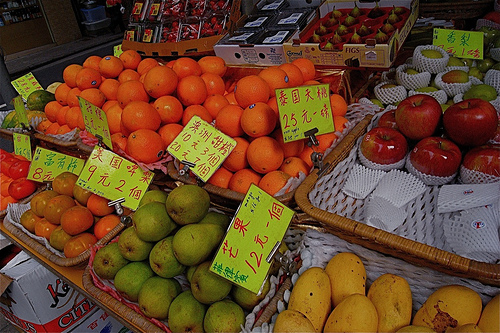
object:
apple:
[355, 121, 414, 170]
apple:
[392, 91, 447, 142]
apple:
[371, 104, 404, 134]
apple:
[440, 89, 500, 148]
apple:
[406, 131, 465, 189]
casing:
[356, 144, 407, 173]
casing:
[403, 153, 460, 189]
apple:
[458, 137, 500, 188]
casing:
[457, 164, 500, 187]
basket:
[289, 93, 500, 289]